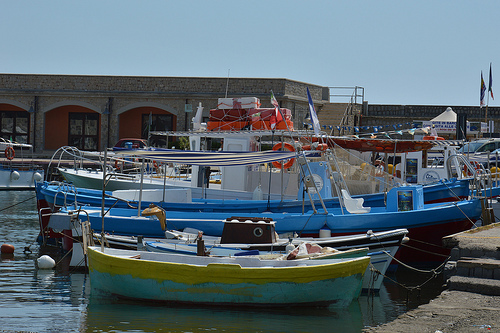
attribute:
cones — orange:
[438, 99, 443, 107]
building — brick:
[2, 64, 333, 165]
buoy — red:
[1, 240, 16, 255]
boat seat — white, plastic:
[341, 189, 371, 213]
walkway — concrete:
[446, 222, 498, 291]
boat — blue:
[78, 244, 373, 306]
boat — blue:
[39, 180, 471, 227]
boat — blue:
[139, 230, 398, 265]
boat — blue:
[55, 123, 362, 173]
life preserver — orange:
[271, 142, 296, 167]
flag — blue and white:
[302, 84, 322, 142]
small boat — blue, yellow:
[85, 238, 371, 308]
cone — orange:
[203, 105, 256, 129]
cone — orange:
[250, 101, 292, 128]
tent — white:
[426, 103, 467, 142]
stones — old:
[441, 292, 483, 330]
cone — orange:
[232, 113, 293, 155]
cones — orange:
[208, 100, 297, 125]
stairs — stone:
[447, 237, 497, 304]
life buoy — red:
[4, 144, 14, 160]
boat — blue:
[30, 83, 487, 275]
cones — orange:
[214, 91, 332, 133]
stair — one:
[441, 275, 483, 296]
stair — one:
[456, 256, 485, 279]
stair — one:
[463, 245, 483, 258]